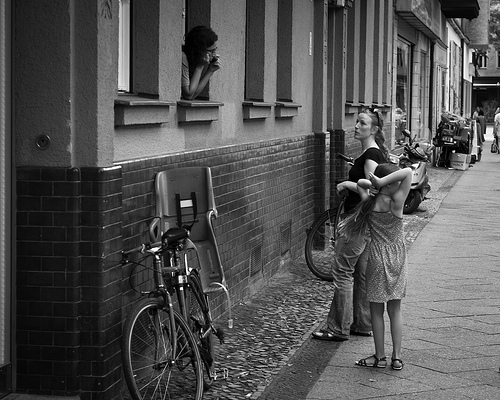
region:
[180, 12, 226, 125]
a woman with her head and arms out a window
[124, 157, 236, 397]
a bicycle leaning against a building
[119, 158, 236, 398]
a bicycle with a child seat on the back of it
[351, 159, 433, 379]
a girl with her arms and hands behind her head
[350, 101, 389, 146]
the head of a woman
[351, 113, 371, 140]
the face of a woman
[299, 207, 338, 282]
the wheel of a bicycle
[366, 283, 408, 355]
the legs of a girl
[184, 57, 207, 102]
the arm of a woman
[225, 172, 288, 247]
the bricks of a wall of a building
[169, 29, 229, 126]
woman hanging on ledge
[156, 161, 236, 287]
car seat on back of bike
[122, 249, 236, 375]
bike parked against wall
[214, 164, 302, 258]
subway tile on bottom of building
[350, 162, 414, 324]
little girl holding her hair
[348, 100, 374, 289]
blonde woman talking to another woman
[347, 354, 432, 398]
black sandals on young girl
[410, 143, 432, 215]
motorcycle parked in fron of building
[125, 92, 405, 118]
a row of window sils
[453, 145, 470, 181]
carboard moving box on floor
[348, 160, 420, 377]
a young girl standing by her mom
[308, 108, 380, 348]
an older woman standing by the building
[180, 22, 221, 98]
a woman looking out the window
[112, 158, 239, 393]
a bike with a baby seat in the back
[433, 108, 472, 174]
a bike with luggage around it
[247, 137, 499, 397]
a sidewalk for people to walk on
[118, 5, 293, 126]
some window on the building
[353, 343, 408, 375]
the sandals the girl is wearing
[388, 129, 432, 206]
a scooter parked next to the building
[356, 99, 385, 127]
the sunglasses on the woman's head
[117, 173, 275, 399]
a bicycle is up against the building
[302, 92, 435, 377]
the two ladies are speaking to the lady in the window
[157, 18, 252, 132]
the woman is hanging out her window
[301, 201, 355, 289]
here is a bicycle tire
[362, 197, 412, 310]
this girl is wearing a dress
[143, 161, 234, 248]
the bicycle has a child seat on it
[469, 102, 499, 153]
a few other people are further down the sidewalk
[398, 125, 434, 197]
a scooter can be seen in the background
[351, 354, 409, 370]
the girl is wearing sandals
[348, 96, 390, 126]
this woman has sunglasses on top of her head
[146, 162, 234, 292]
Child seat on bicycle.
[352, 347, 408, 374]
Sandals on the feet.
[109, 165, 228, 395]
Bicycle leaning against the wall.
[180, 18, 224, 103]
Person leaning out the window.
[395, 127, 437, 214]
Scooter parked on the walk.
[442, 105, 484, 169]
Clothing on the street.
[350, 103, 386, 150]
Sun glasses on the woman's head.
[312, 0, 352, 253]
Door in the building.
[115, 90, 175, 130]
Window ledge on the building.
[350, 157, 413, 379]
Long brown hair on the girl.